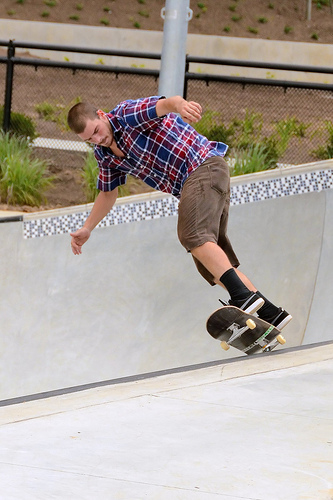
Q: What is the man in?
A: Shorts.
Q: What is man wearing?
A: Socks.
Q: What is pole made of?
A: Metal.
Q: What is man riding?
A: Skateboard.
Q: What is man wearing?
A: Shorts.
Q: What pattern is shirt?
A: Striped.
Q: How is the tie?
A: Decorative.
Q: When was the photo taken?
A: During the daytime.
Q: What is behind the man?
A: Black fence.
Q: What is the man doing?
A: Skating.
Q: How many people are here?
A: One.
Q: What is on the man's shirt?
A: Plaid.